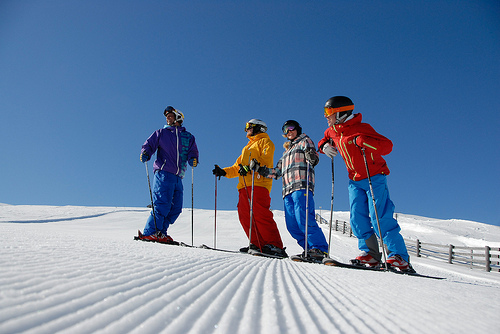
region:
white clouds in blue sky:
[38, 15, 88, 50]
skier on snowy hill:
[120, 100, 212, 245]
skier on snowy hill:
[195, 110, 276, 261]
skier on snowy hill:
[281, 116, 331, 291]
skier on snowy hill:
[300, 95, 405, 297]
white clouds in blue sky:
[55, 63, 96, 130]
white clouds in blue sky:
[163, 56, 212, 87]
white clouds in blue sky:
[446, 99, 490, 127]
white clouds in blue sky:
[346, 33, 435, 83]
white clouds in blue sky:
[202, 51, 239, 96]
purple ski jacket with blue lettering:
[134, 123, 202, 174]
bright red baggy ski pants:
[224, 182, 285, 246]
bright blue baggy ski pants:
[340, 174, 411, 256]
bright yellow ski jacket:
[219, 132, 280, 197]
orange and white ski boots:
[130, 220, 182, 246]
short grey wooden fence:
[310, 206, 498, 270]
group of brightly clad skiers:
[116, 88, 433, 282]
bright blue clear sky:
[4, 0, 498, 229]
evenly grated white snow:
[0, 199, 497, 330]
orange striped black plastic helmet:
[322, 93, 357, 125]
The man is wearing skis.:
[119, 78, 204, 255]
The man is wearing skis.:
[203, 105, 293, 268]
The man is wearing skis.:
[313, 90, 434, 283]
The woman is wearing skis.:
[256, 110, 340, 276]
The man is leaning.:
[311, 90, 435, 298]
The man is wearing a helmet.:
[309, 87, 429, 284]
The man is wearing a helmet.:
[207, 102, 287, 265]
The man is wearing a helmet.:
[126, 96, 206, 251]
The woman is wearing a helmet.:
[250, 114, 332, 268]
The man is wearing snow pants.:
[116, 88, 206, 252]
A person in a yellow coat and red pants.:
[211, 115, 286, 254]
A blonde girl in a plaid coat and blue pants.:
[250, 118, 330, 258]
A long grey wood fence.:
[311, 213, 499, 272]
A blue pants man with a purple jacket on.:
[138, 105, 199, 242]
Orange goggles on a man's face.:
[321, 102, 353, 116]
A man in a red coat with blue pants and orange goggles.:
[315, 95, 411, 267]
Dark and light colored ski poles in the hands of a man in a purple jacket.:
[143, 150, 196, 247]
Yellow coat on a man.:
[221, 134, 273, 189]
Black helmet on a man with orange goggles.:
[324, 93, 353, 115]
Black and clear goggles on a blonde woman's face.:
[280, 122, 300, 135]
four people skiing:
[83, 43, 445, 310]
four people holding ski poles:
[120, 82, 477, 292]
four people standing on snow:
[99, 82, 459, 299]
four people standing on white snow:
[79, 95, 454, 305]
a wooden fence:
[351, 209, 498, 274]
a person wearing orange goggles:
[303, 81, 410, 206]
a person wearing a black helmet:
[295, 82, 394, 175]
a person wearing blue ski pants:
[126, 94, 208, 259]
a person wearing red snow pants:
[203, 100, 291, 272]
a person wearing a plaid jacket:
[266, 122, 335, 251]